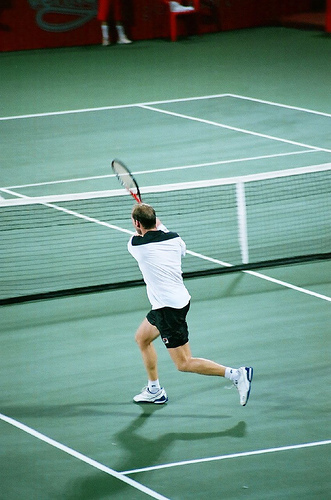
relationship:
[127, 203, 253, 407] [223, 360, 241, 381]
man wearing socks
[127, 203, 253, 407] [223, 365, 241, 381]
man wearing sock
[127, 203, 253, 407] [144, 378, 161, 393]
man wearing sock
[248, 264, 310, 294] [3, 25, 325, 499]
line on court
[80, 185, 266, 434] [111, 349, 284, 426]
man wearing shoes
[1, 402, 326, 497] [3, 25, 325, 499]
paint on court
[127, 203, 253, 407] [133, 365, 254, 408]
man wearing a pair of shoes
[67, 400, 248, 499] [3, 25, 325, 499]
shadow on court